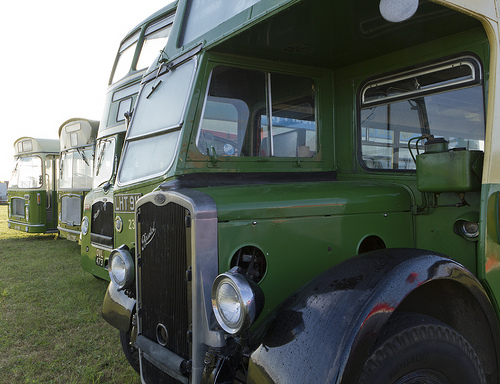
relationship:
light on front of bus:
[215, 279, 245, 330] [102, 0, 500, 383]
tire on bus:
[354, 312, 488, 383] [102, 0, 500, 383]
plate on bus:
[112, 194, 143, 213] [102, 0, 500, 383]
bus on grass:
[102, 0, 500, 383] [1, 204, 141, 384]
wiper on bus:
[145, 61, 166, 102] [102, 0, 500, 383]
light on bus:
[110, 255, 126, 288] [102, 0, 500, 383]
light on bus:
[215, 279, 245, 330] [102, 0, 500, 383]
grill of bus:
[137, 201, 191, 357] [102, 0, 500, 383]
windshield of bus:
[128, 58, 197, 139] [102, 0, 500, 383]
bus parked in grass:
[102, 0, 500, 383] [1, 204, 141, 384]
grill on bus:
[137, 201, 191, 357] [102, 0, 500, 383]